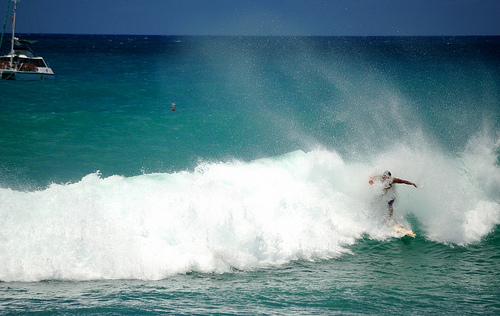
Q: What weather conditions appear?
A: It is clear.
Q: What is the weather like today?
A: It is clear.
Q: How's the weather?
A: It is clear.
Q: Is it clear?
A: Yes, it is clear.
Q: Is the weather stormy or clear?
A: It is clear.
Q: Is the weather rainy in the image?
A: No, it is clear.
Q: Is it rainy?
A: No, it is clear.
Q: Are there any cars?
A: No, there are no cars.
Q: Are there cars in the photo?
A: No, there are no cars.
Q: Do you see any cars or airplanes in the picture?
A: No, there are no cars or airplanes.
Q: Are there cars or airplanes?
A: No, there are no cars or airplanes.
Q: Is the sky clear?
A: Yes, the sky is clear.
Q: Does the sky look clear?
A: Yes, the sky is clear.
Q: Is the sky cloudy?
A: No, the sky is clear.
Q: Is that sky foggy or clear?
A: The sky is clear.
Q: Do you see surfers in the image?
A: Yes, there is a surfer.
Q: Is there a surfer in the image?
A: Yes, there is a surfer.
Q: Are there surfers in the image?
A: Yes, there is a surfer.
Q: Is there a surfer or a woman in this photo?
A: Yes, there is a surfer.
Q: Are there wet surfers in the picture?
A: Yes, there is a wet surfer.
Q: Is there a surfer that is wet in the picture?
A: Yes, there is a wet surfer.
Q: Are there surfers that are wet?
A: Yes, there is a surfer that is wet.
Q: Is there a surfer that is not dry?
A: Yes, there is a wet surfer.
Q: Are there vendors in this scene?
A: No, there are no vendors.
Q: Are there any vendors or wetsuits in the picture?
A: No, there are no vendors or wetsuits.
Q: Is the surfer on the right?
A: Yes, the surfer is on the right of the image.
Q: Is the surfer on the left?
A: No, the surfer is on the right of the image.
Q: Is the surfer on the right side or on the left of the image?
A: The surfer is on the right of the image.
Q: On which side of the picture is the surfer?
A: The surfer is on the right of the image.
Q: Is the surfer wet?
A: Yes, the surfer is wet.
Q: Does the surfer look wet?
A: Yes, the surfer is wet.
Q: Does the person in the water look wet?
A: Yes, the surfer is wet.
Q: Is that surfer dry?
A: No, the surfer is wet.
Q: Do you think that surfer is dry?
A: No, the surfer is wet.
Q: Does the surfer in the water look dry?
A: No, the surfer is wet.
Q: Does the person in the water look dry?
A: No, the surfer is wet.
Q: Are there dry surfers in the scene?
A: No, there is a surfer but he is wet.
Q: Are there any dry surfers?
A: No, there is a surfer but he is wet.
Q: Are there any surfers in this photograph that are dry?
A: No, there is a surfer but he is wet.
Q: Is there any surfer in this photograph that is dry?
A: No, there is a surfer but he is wet.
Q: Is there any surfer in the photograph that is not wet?
A: No, there is a surfer but he is wet.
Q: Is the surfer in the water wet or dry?
A: The surfer is wet.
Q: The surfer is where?
A: The surfer is in the water.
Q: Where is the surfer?
A: The surfer is in the water.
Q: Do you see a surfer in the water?
A: Yes, there is a surfer in the water.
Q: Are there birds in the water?
A: No, there is a surfer in the water.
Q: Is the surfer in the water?
A: Yes, the surfer is in the water.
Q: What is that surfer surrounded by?
A: The surfer is surrounded by the water.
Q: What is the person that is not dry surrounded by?
A: The surfer is surrounded by the water.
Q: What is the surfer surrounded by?
A: The surfer is surrounded by the water.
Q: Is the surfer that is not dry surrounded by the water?
A: Yes, the surfer is surrounded by the water.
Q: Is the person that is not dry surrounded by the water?
A: Yes, the surfer is surrounded by the water.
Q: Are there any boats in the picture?
A: Yes, there is a boat.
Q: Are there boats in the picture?
A: Yes, there is a boat.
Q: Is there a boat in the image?
A: Yes, there is a boat.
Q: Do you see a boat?
A: Yes, there is a boat.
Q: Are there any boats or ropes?
A: Yes, there is a boat.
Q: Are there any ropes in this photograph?
A: No, there are no ropes.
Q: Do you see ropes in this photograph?
A: No, there are no ropes.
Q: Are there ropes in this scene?
A: No, there are no ropes.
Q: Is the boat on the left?
A: Yes, the boat is on the left of the image.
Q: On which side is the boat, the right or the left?
A: The boat is on the left of the image.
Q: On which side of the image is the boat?
A: The boat is on the left of the image.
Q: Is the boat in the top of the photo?
A: Yes, the boat is in the top of the image.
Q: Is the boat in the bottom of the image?
A: No, the boat is in the top of the image.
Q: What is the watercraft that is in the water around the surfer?
A: The watercraft is a boat.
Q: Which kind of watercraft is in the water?
A: The watercraft is a boat.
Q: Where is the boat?
A: The boat is in the water.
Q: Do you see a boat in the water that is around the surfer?
A: Yes, there is a boat in the water.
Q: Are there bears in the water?
A: No, there is a boat in the water.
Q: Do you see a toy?
A: No, there are no toys.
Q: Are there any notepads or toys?
A: No, there are no toys or notepads.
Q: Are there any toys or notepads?
A: No, there are no toys or notepads.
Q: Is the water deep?
A: Yes, the water is deep.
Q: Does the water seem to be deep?
A: Yes, the water is deep.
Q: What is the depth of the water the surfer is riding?
A: The water is deep.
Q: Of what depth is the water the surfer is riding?
A: The water is deep.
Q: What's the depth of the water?
A: The water is deep.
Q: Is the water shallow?
A: No, the water is deep.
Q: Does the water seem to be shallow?
A: No, the water is deep.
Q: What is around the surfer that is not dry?
A: The water is around the surfer.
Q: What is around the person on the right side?
A: The water is around the surfer.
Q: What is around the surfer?
A: The water is around the surfer.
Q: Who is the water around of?
A: The water is around the surfer.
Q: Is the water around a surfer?
A: Yes, the water is around a surfer.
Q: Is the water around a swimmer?
A: No, the water is around a surfer.